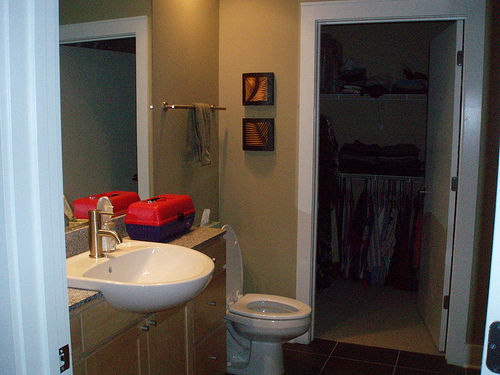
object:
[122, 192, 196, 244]
carryall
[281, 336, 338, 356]
tiles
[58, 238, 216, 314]
sink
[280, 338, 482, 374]
floor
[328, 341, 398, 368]
tile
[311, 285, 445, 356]
floor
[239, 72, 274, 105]
pictures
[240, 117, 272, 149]
pictures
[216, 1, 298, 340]
wall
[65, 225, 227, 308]
counter top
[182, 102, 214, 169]
towel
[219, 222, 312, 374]
toilet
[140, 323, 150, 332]
metal knob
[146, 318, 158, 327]
metal knob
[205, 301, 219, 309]
metal knob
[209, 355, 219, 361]
metal knob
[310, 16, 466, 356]
closet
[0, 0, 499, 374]
bathroom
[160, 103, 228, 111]
towel bar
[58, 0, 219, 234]
wall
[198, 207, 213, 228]
tissues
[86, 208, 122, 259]
fixtures